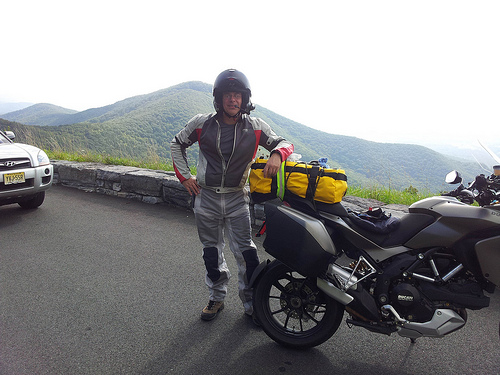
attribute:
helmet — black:
[211, 68, 251, 90]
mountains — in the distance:
[1, 77, 499, 199]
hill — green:
[99, 89, 282, 179]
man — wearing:
[176, 73, 298, 278]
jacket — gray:
[169, 107, 283, 179]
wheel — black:
[242, 246, 353, 350]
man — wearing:
[180, 44, 290, 350]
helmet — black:
[211, 68, 252, 103]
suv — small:
[1, 123, 53, 213]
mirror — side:
[437, 167, 477, 189]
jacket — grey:
[162, 109, 287, 211]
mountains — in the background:
[97, 74, 498, 258]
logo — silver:
[3, 157, 20, 171]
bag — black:
[249, 151, 354, 206]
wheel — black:
[250, 236, 378, 366]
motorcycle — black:
[248, 168, 498, 346]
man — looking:
[168, 65, 294, 325]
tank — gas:
[267, 222, 322, 281]